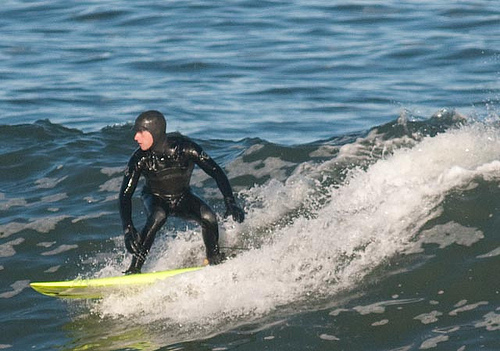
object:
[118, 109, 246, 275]
man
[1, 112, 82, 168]
wave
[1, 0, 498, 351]
ocean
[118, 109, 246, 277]
wetsuit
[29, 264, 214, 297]
surfboard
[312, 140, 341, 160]
foam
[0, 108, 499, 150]
crest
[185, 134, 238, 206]
arm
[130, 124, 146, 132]
hair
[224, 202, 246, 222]
glove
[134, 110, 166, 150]
hood